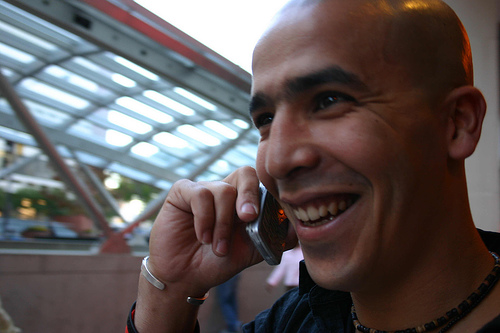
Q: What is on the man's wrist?
A: A bracelet.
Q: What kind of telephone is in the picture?
A: A cellular phone.